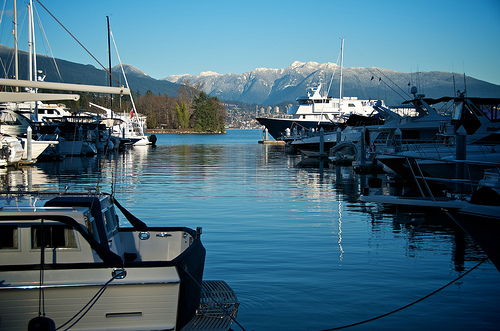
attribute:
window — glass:
[298, 97, 313, 106]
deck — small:
[189, 276, 240, 328]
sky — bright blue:
[0, 0, 495, 98]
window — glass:
[319, 97, 329, 102]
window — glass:
[43, 108, 58, 117]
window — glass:
[33, 227, 71, 245]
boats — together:
[258, 96, 497, 222]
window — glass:
[377, 127, 432, 147]